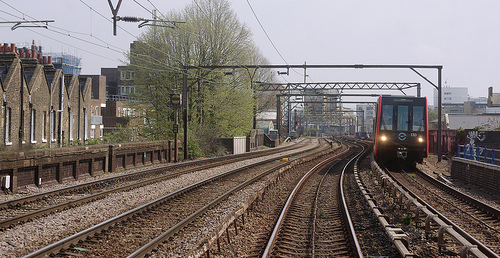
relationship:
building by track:
[0, 43, 32, 149] [3, 137, 290, 224]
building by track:
[25, 60, 54, 159] [3, 137, 290, 224]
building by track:
[50, 63, 71, 144] [3, 137, 290, 224]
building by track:
[68, 74, 84, 146] [3, 137, 290, 224]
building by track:
[82, 73, 105, 143] [3, 137, 290, 224]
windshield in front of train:
[376, 99, 429, 135] [366, 95, 466, 180]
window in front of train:
[390, 96, 416, 106] [368, 85, 430, 167]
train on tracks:
[373, 94, 429, 164] [398, 168, 463, 223]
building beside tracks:
[2, 40, 116, 168] [4, 130, 345, 257]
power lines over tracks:
[79, 0, 237, 73] [0, 160, 447, 252]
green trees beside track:
[117, 0, 255, 145] [1, 133, 313, 231]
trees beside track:
[188, 80, 257, 150] [1, 133, 313, 231]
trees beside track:
[218, 37, 285, 115] [1, 133, 313, 231]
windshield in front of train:
[376, 99, 429, 135] [364, 87, 442, 169]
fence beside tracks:
[4, 138, 194, 179] [2, 135, 315, 230]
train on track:
[335, 74, 460, 174] [9, 117, 483, 243]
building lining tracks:
[0, 43, 32, 149] [2, 135, 315, 230]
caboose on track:
[338, 57, 455, 165] [365, 153, 495, 254]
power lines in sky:
[0, 3, 304, 88] [6, 2, 493, 97]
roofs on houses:
[0, 62, 108, 99] [0, 48, 109, 148]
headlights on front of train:
[379, 130, 427, 145] [358, 90, 431, 166]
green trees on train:
[182, 15, 252, 150] [362, 78, 459, 173]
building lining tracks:
[17, 47, 52, 146] [1, 136, 498, 254]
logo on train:
[396, 130, 411, 143] [364, 86, 436, 171]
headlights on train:
[379, 134, 425, 144] [370, 92, 427, 165]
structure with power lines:
[264, 77, 365, 95] [59, 27, 106, 59]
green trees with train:
[117, 0, 255, 145] [370, 92, 437, 173]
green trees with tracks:
[117, 0, 255, 145] [337, 155, 469, 244]